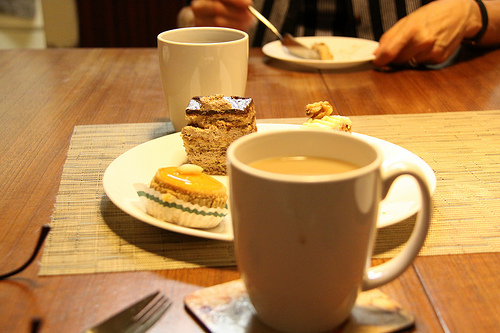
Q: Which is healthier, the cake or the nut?
A: The nut is healthier than the cake.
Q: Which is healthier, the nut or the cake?
A: The nut is healthier than the cake.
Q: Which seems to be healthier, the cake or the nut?
A: The nut is healthier than the cake.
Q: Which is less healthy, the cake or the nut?
A: The cake is less healthy than the nut.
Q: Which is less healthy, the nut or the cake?
A: The cake is less healthy than the nut.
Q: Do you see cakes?
A: Yes, there is a cake.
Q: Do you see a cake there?
A: Yes, there is a cake.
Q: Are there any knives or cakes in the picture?
A: Yes, there is a cake.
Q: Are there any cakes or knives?
A: Yes, there is a cake.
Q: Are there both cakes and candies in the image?
A: No, there is a cake but no candies.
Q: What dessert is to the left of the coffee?
A: The dessert is a cake.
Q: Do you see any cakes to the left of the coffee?
A: Yes, there is a cake to the left of the coffee.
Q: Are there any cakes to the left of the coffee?
A: Yes, there is a cake to the left of the coffee.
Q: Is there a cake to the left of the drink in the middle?
A: Yes, there is a cake to the left of the coffee.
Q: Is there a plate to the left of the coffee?
A: No, there is a cake to the left of the coffee.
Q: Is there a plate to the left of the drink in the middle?
A: No, there is a cake to the left of the coffee.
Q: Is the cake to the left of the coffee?
A: Yes, the cake is to the left of the coffee.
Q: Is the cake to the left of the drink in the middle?
A: Yes, the cake is to the left of the coffee.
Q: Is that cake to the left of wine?
A: No, the cake is to the left of the coffee.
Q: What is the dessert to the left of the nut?
A: The dessert is a cake.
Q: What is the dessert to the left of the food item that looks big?
A: The dessert is a cake.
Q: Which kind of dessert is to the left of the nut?
A: The dessert is a cake.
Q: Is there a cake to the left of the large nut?
A: Yes, there is a cake to the left of the nut.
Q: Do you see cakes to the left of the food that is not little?
A: Yes, there is a cake to the left of the nut.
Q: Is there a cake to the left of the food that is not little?
A: Yes, there is a cake to the left of the nut.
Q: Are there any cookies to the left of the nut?
A: No, there is a cake to the left of the nut.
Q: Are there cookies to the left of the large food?
A: No, there is a cake to the left of the nut.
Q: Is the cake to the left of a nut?
A: Yes, the cake is to the left of a nut.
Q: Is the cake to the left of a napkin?
A: No, the cake is to the left of a nut.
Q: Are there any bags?
A: No, there are no bags.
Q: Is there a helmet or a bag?
A: No, there are no bags or helmets.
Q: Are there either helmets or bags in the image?
A: No, there are no bags or helmets.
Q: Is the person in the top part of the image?
A: Yes, the person is in the top of the image.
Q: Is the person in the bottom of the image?
A: No, the person is in the top of the image.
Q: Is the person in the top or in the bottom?
A: The person is in the top of the image.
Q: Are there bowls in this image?
A: No, there are no bowls.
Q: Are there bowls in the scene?
A: No, there are no bowls.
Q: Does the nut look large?
A: Yes, the nut is large.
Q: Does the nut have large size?
A: Yes, the nut is large.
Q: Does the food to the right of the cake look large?
A: Yes, the nut is large.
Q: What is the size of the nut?
A: The nut is large.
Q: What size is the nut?
A: The nut is large.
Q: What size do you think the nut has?
A: The nut has large size.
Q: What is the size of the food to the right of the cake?
A: The nut is large.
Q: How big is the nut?
A: The nut is large.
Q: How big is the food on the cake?
A: The nut is large.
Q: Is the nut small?
A: No, the nut is large.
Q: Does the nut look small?
A: No, the nut is large.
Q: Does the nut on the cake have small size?
A: No, the nut is large.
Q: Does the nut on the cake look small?
A: No, the nut is large.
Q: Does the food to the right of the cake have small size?
A: No, the nut is large.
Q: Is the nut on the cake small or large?
A: The nut is large.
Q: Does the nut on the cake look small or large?
A: The nut is large.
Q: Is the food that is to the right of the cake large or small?
A: The nut is large.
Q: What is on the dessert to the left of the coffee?
A: The nut is on the cake.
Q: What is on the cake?
A: The nut is on the cake.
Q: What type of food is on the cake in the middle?
A: The food is a nut.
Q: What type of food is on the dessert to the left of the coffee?
A: The food is a nut.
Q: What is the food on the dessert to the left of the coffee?
A: The food is a nut.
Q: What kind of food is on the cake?
A: The food is a nut.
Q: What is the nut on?
A: The nut is on the cake.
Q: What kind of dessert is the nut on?
A: The nut is on the cake.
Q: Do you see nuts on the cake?
A: Yes, there is a nut on the cake.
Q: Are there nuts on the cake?
A: Yes, there is a nut on the cake.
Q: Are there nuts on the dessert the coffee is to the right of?
A: Yes, there is a nut on the cake.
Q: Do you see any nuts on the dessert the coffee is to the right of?
A: Yes, there is a nut on the cake.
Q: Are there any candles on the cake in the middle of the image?
A: No, there is a nut on the cake.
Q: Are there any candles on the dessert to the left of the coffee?
A: No, there is a nut on the cake.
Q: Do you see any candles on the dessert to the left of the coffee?
A: No, there is a nut on the cake.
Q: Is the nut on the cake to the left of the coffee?
A: Yes, the nut is on the cake.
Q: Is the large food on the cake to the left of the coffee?
A: Yes, the nut is on the cake.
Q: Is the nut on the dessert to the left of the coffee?
A: Yes, the nut is on the cake.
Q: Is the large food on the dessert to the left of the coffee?
A: Yes, the nut is on the cake.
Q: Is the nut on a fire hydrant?
A: No, the nut is on the cake.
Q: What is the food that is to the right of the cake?
A: The food is a nut.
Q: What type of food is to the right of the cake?
A: The food is a nut.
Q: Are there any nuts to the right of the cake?
A: Yes, there is a nut to the right of the cake.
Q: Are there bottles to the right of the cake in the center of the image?
A: No, there is a nut to the right of the cake.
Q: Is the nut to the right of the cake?
A: Yes, the nut is to the right of the cake.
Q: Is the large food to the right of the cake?
A: Yes, the nut is to the right of the cake.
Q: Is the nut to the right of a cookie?
A: No, the nut is to the right of the cake.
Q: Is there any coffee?
A: Yes, there is coffee.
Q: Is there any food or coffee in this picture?
A: Yes, there is coffee.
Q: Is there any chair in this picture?
A: No, there are no chairs.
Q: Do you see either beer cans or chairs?
A: No, there are no chairs or beer cans.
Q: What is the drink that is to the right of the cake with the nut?
A: The drink is coffee.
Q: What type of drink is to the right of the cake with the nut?
A: The drink is coffee.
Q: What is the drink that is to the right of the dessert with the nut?
A: The drink is coffee.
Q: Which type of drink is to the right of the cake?
A: The drink is coffee.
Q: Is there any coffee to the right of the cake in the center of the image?
A: Yes, there is coffee to the right of the cake.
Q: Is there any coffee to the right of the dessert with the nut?
A: Yes, there is coffee to the right of the cake.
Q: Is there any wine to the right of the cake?
A: No, there is coffee to the right of the cake.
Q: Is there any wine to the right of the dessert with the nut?
A: No, there is coffee to the right of the cake.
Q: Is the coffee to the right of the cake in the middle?
A: Yes, the coffee is to the right of the cake.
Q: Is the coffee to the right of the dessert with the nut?
A: Yes, the coffee is to the right of the cake.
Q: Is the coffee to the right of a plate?
A: No, the coffee is to the right of the cake.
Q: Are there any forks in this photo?
A: Yes, there is a fork.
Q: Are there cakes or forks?
A: Yes, there is a fork.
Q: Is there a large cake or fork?
A: Yes, there is a large fork.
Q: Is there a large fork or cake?
A: Yes, there is a large fork.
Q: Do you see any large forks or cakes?
A: Yes, there is a large fork.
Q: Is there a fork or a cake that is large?
A: Yes, the fork is large.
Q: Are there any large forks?
A: Yes, there is a large fork.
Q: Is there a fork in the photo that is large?
A: Yes, there is a fork that is large.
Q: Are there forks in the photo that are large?
A: Yes, there is a fork that is large.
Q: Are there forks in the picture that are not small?
A: Yes, there is a large fork.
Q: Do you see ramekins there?
A: No, there are no ramekins.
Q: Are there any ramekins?
A: No, there are no ramekins.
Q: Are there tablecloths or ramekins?
A: No, there are no ramekins or tablecloths.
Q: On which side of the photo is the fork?
A: The fork is on the left of the image.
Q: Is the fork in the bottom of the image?
A: Yes, the fork is in the bottom of the image.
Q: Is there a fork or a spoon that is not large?
A: No, there is a fork but it is large.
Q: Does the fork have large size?
A: Yes, the fork is large.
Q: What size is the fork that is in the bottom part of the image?
A: The fork is large.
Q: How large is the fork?
A: The fork is large.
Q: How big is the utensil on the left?
A: The fork is large.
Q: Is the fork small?
A: No, the fork is large.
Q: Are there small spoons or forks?
A: No, there is a fork but it is large.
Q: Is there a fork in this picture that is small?
A: No, there is a fork but it is large.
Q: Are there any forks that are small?
A: No, there is a fork but it is large.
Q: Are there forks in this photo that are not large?
A: No, there is a fork but it is large.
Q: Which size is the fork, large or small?
A: The fork is large.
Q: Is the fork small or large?
A: The fork is large.